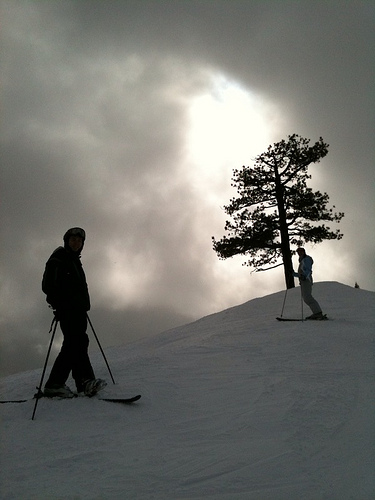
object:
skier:
[41, 227, 104, 398]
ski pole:
[83, 312, 115, 385]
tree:
[211, 132, 344, 292]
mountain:
[0, 281, 375, 499]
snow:
[222, 350, 333, 499]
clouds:
[90, 47, 194, 194]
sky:
[1, 2, 374, 354]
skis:
[0, 393, 142, 405]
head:
[63, 226, 86, 256]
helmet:
[63, 227, 86, 241]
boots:
[42, 379, 76, 400]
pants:
[44, 309, 95, 392]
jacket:
[41, 246, 92, 315]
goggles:
[64, 236, 87, 245]